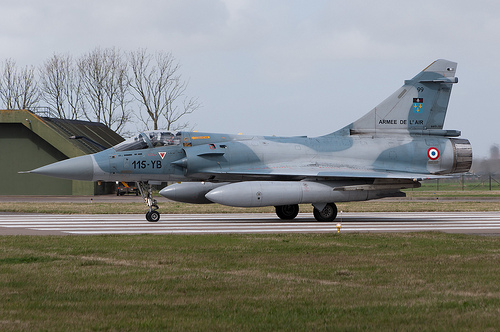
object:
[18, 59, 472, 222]
jet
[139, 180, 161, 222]
landing gear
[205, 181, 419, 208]
missiles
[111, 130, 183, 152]
cockpit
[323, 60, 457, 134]
tail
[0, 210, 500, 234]
runway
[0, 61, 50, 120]
trees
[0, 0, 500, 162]
sky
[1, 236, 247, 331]
grass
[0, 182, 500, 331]
ground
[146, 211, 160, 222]
wheels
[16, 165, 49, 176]
nose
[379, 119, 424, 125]
words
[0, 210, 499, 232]
marks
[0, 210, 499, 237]
lines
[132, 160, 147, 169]
numbers